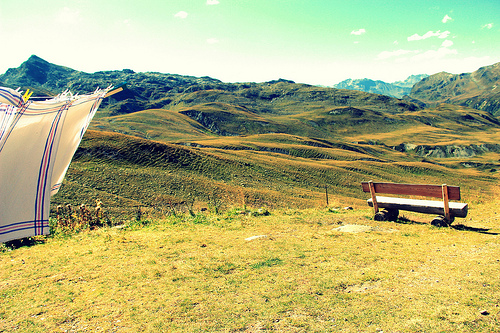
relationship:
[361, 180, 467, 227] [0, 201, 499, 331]
bench in field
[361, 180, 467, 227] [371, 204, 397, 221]
bench has wheels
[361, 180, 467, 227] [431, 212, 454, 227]
bench has wheels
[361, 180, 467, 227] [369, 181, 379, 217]
bench has stick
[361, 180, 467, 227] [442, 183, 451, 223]
bench has stick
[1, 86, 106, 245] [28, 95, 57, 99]
blanket on string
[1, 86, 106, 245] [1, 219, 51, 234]
blanket has stripes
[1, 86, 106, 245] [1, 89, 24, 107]
blanket has stripes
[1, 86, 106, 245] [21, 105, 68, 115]
blanket has stripes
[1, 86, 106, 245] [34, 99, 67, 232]
blanket has stripes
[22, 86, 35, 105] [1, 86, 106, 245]
clothespin holding blanket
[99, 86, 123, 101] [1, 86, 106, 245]
clothespin holding blanket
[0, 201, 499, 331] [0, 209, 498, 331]
field has grass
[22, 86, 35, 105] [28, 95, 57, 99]
clothespin on string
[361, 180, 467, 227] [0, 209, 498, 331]
bench in grass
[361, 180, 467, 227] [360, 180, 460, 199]
bench has back rest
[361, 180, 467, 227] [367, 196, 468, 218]
bench has seat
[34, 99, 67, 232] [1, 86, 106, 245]
stripes on blanket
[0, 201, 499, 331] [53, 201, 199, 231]
field has fence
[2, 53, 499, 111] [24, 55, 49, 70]
mountains have peak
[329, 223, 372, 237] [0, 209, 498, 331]
spot in grass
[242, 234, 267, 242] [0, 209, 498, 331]
spot in grass